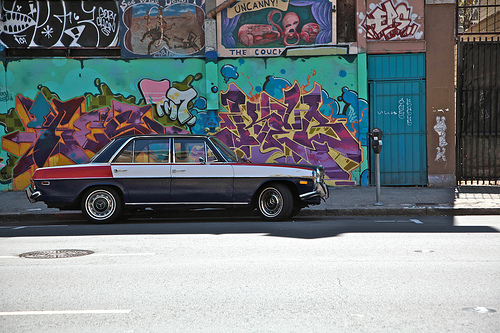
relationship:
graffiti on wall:
[1, 76, 369, 187] [0, 1, 371, 190]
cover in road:
[20, 248, 98, 260] [0, 222, 499, 332]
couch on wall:
[236, 25, 281, 49] [0, 1, 371, 190]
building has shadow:
[2, 1, 458, 193] [0, 189, 499, 238]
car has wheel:
[27, 133, 330, 223] [256, 181, 294, 220]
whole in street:
[19, 245, 93, 260] [0, 224, 499, 332]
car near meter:
[27, 133, 330, 223] [368, 127, 387, 207]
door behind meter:
[366, 52, 430, 187] [368, 127, 387, 207]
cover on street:
[20, 248, 98, 260] [0, 224, 499, 332]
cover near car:
[20, 248, 98, 260] [27, 133, 330, 223]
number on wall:
[166, 89, 198, 127] [0, 1, 371, 190]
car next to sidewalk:
[27, 133, 330, 223] [3, 188, 500, 225]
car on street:
[27, 133, 330, 223] [0, 224, 499, 332]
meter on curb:
[368, 127, 387, 207] [358, 192, 408, 215]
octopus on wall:
[266, 11, 311, 49] [0, 1, 371, 190]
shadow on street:
[0, 189, 499, 238] [0, 224, 499, 332]